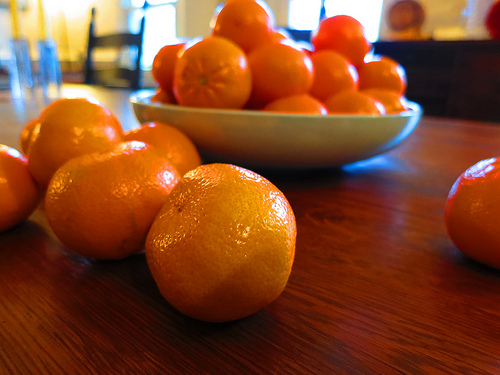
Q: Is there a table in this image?
A: Yes, there is a table.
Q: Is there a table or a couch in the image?
A: Yes, there is a table.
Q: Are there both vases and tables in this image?
A: No, there is a table but no vases.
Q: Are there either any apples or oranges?
A: Yes, there are oranges.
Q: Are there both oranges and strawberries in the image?
A: No, there are oranges but no strawberries.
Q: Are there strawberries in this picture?
A: No, there are no strawberries.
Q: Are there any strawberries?
A: No, there are no strawberries.